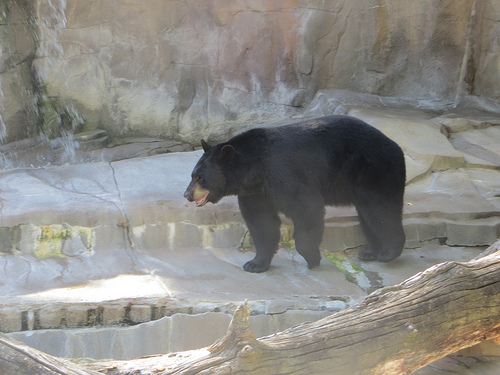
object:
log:
[0, 254, 483, 375]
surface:
[203, 274, 363, 301]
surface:
[92, 249, 243, 305]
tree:
[0, 239, 499, 374]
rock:
[0, 0, 499, 164]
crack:
[45, 7, 337, 120]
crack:
[2, 3, 50, 122]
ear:
[218, 145, 236, 165]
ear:
[200, 138, 212, 153]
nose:
[183, 180, 196, 202]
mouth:
[190, 191, 209, 207]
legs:
[237, 193, 327, 274]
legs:
[353, 188, 405, 262]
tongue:
[195, 197, 203, 203]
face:
[191, 145, 228, 205]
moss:
[31, 87, 96, 137]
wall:
[0, 0, 499, 117]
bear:
[182, 115, 406, 273]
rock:
[0, 154, 499, 359]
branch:
[0, 245, 499, 374]